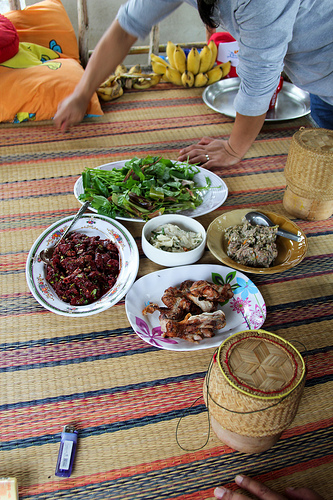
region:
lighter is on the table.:
[55, 421, 80, 475]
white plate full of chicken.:
[130, 267, 263, 338]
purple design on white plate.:
[134, 317, 173, 346]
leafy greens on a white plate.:
[79, 156, 211, 214]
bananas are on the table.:
[150, 40, 233, 87]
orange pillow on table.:
[0, 2, 100, 124]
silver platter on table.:
[202, 72, 312, 119]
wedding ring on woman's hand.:
[204, 153, 211, 161]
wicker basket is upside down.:
[207, 332, 302, 434]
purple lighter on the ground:
[53, 423, 80, 474]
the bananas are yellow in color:
[150, 38, 231, 82]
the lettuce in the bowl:
[72, 157, 227, 214]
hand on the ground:
[177, 137, 238, 167]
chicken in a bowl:
[122, 263, 263, 349]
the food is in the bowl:
[206, 204, 307, 274]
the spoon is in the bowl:
[245, 209, 302, 242]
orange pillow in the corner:
[0, 0, 106, 117]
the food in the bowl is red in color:
[24, 213, 137, 313]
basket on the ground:
[203, 328, 307, 454]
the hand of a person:
[42, 86, 91, 143]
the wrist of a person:
[41, 72, 118, 143]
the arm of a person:
[26, 2, 193, 178]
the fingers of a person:
[179, 116, 235, 190]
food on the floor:
[45, 155, 245, 350]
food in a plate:
[101, 211, 312, 338]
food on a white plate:
[34, 195, 166, 321]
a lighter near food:
[36, 419, 103, 483]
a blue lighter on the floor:
[51, 394, 126, 479]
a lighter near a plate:
[45, 251, 255, 477]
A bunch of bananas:
[96, 34, 233, 94]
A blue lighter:
[55, 424, 84, 478]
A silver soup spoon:
[242, 206, 302, 246]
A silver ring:
[203, 152, 212, 162]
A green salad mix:
[73, 152, 230, 220]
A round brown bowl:
[206, 208, 307, 275]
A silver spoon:
[38, 199, 98, 262]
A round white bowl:
[139, 212, 207, 266]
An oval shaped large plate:
[59, 153, 235, 222]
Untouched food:
[10, 148, 313, 384]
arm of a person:
[85, 5, 163, 77]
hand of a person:
[43, 92, 86, 146]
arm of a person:
[220, 11, 294, 135]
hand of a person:
[179, 130, 238, 172]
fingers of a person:
[180, 127, 229, 176]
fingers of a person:
[222, 470, 282, 498]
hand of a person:
[201, 468, 318, 496]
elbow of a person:
[261, 76, 285, 95]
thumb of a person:
[59, 116, 82, 135]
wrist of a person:
[218, 128, 250, 163]